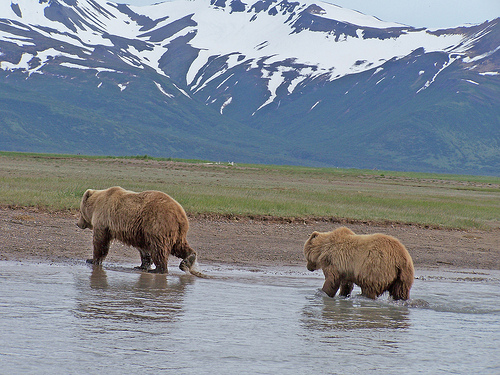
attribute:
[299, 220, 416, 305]
bear — bottom 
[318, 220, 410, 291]
bear — brown, large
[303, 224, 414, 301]
bear — facing downward 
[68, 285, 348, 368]
water —  calm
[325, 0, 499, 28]
blue sky — blue 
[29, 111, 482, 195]
landscape — grassy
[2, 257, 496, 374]
water — part, small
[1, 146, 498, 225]
field — edge 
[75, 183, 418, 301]
bears — two brown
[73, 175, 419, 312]
bears — brown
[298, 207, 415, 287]
bear — very fluffy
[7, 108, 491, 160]
grass — lots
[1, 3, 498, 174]
mountains — distance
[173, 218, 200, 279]
tail — short 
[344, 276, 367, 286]
belly — bears, wet